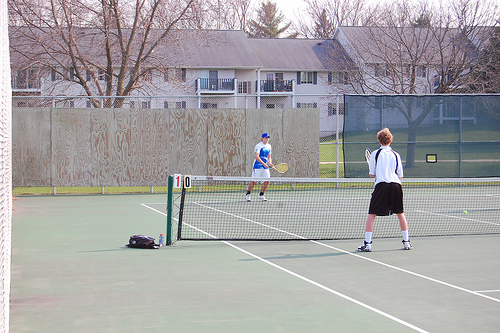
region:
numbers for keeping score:
[171, 175, 191, 186]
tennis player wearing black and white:
[360, 128, 411, 254]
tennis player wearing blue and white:
[243, 130, 286, 197]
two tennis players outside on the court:
[244, 129, 413, 258]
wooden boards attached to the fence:
[21, 109, 228, 169]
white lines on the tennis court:
[311, 261, 492, 329]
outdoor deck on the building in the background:
[193, 73, 241, 92]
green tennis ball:
[459, 210, 467, 215]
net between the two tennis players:
[193, 173, 318, 247]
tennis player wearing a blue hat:
[246, 130, 283, 200]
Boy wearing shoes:
[355, 235, 415, 252]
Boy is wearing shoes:
[355, 237, 417, 254]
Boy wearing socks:
[364, 226, 411, 243]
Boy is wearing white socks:
[360, 228, 411, 246]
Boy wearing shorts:
[362, 176, 409, 218]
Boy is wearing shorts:
[363, 179, 410, 219]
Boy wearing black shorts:
[362, 180, 409, 220]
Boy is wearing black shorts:
[368, 178, 409, 221]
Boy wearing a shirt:
[367, 141, 409, 188]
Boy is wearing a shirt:
[365, 145, 407, 190]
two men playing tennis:
[245, 128, 411, 249]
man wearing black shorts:
[367, 185, 403, 215]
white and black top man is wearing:
[367, 147, 403, 182]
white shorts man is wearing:
[250, 165, 268, 180]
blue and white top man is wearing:
[250, 142, 273, 165]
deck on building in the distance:
[252, 71, 294, 92]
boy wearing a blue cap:
[258, 131, 269, 137]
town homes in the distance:
[10, 26, 496, 136]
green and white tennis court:
[15, 181, 497, 327]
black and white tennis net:
[178, 175, 498, 242]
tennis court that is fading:
[51, 222, 125, 308]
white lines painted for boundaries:
[242, 255, 497, 326]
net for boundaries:
[160, 169, 499, 243]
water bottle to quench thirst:
[156, 233, 166, 245]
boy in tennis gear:
[363, 125, 408, 255]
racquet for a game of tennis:
[268, 161, 290, 173]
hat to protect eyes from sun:
[259, 130, 271, 142]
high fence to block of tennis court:
[338, 93, 490, 175]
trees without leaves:
[13, 2, 178, 89]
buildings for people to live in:
[12, 25, 472, 77]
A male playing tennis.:
[356, 128, 412, 252]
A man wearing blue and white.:
[245, 130, 275, 201]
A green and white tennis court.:
[11, 174, 499, 330]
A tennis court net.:
[166, 172, 498, 247]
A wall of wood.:
[11, 104, 320, 189]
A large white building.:
[9, 25, 499, 138]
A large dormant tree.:
[9, 0, 204, 109]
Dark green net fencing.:
[341, 95, 498, 177]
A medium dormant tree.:
[319, 0, 496, 165]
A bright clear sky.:
[8, 1, 499, 40]